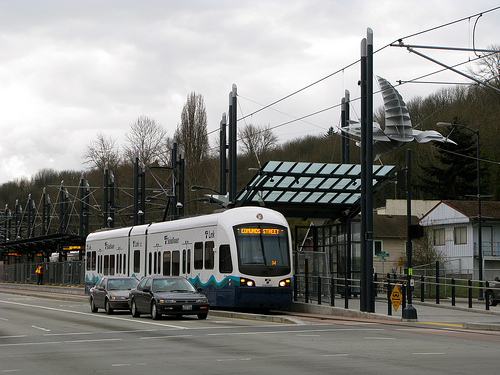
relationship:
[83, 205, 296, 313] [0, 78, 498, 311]
bus stopped at station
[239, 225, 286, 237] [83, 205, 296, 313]
sign on front of bus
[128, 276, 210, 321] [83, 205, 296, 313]
car beside bus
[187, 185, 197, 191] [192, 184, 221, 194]
light at end of pole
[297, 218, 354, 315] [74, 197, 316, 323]
fence near bus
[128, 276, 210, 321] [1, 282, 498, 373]
car going down road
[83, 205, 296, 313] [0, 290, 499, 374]
bus traveling on street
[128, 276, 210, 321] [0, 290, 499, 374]
car traveling on street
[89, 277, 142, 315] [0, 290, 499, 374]
car traveling on street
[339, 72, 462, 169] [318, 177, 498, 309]
sculpture above houses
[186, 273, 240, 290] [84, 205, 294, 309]
wave on side of bus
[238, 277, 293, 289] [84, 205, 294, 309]
lights on bus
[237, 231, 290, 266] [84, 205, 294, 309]
windshield of bus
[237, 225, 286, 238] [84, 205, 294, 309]
digital display on front of bus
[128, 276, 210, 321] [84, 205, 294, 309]
car beside bus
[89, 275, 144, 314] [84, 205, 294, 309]
car beside bus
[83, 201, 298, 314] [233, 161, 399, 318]
bus parked at bus stop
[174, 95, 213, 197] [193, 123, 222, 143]
tree top towering over wire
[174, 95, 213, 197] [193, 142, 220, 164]
tree top towering over wire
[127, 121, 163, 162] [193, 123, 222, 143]
tree top towering over wire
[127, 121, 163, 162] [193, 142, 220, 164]
tree top towering over wire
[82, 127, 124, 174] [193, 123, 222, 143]
tree top towering over wire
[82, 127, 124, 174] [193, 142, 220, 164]
tree top towering over wire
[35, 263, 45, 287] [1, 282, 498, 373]
person on side of road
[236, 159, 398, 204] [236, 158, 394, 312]
roof to shelter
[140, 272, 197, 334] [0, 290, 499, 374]
car stopped in street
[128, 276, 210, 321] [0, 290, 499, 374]
car stopped in street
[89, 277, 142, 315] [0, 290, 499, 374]
car stopped in street